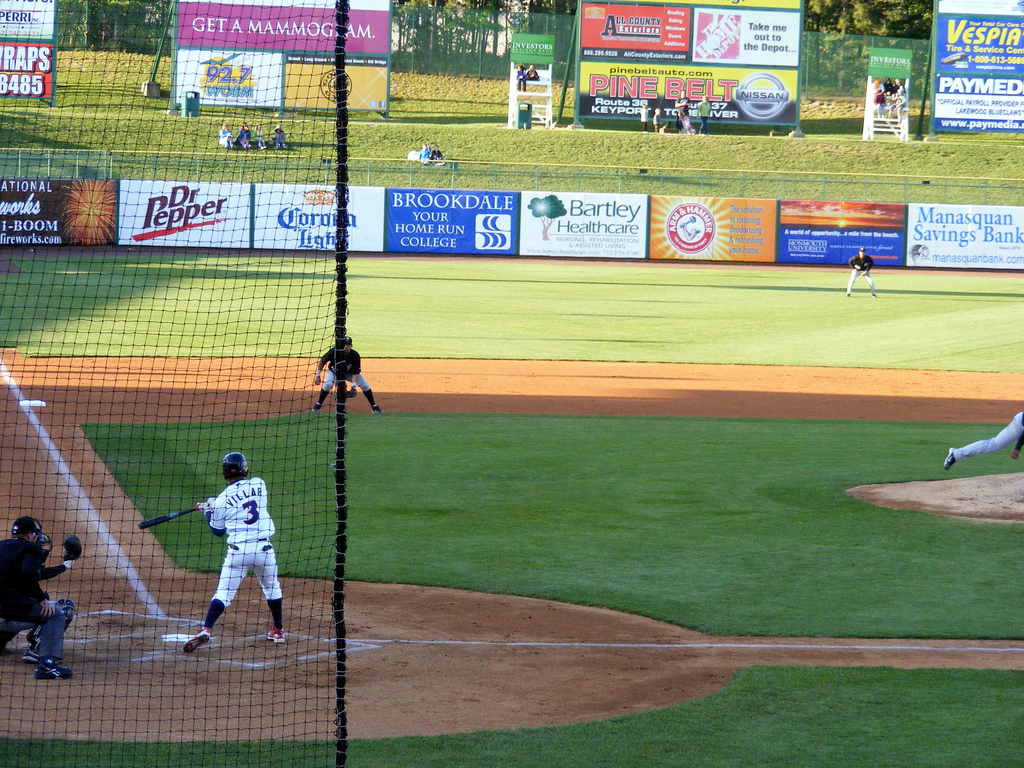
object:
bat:
[135, 503, 207, 532]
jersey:
[208, 475, 276, 538]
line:
[374, 636, 1020, 653]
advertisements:
[3, 182, 1022, 278]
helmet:
[222, 452, 249, 478]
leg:
[944, 408, 1023, 475]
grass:
[2, 250, 1023, 356]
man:
[840, 247, 882, 298]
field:
[0, 282, 1024, 376]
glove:
[63, 533, 82, 561]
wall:
[351, 178, 1005, 274]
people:
[218, 123, 295, 151]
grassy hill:
[175, 92, 328, 166]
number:
[241, 500, 259, 524]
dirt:
[311, 336, 382, 414]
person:
[3, 513, 84, 680]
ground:
[35, 630, 317, 703]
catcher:
[186, 450, 290, 650]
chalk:
[55, 462, 142, 568]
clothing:
[955, 409, 1024, 465]